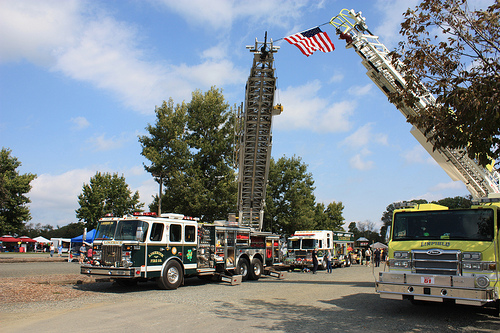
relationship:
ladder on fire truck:
[237, 32, 283, 231] [81, 11, 285, 288]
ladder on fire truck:
[330, 9, 500, 202] [329, 8, 500, 314]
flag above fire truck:
[285, 25, 335, 55] [81, 11, 285, 288]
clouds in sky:
[0, 0, 500, 238] [1, 0, 500, 236]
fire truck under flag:
[329, 8, 500, 314] [285, 25, 335, 55]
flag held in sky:
[285, 25, 335, 55] [1, 0, 500, 236]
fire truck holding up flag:
[81, 11, 285, 288] [285, 25, 335, 55]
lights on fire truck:
[131, 211, 159, 217] [81, 11, 285, 288]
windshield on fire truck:
[95, 219, 148, 243] [81, 11, 285, 288]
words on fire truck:
[148, 250, 165, 265] [81, 11, 285, 288]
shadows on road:
[212, 277, 500, 331] [1, 251, 499, 332]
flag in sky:
[285, 25, 335, 55] [1, 0, 500, 236]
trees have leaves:
[1, 1, 499, 257] [1, 0, 500, 251]